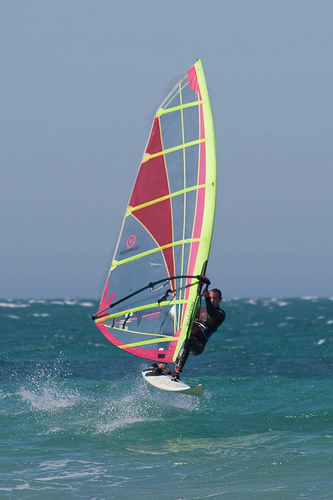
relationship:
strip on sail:
[144, 132, 209, 155] [125, 90, 212, 359]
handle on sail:
[150, 274, 195, 299] [125, 90, 212, 359]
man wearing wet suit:
[193, 288, 221, 376] [184, 312, 220, 357]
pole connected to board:
[152, 363, 166, 374] [145, 379, 198, 395]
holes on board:
[136, 367, 171, 382] [145, 379, 198, 395]